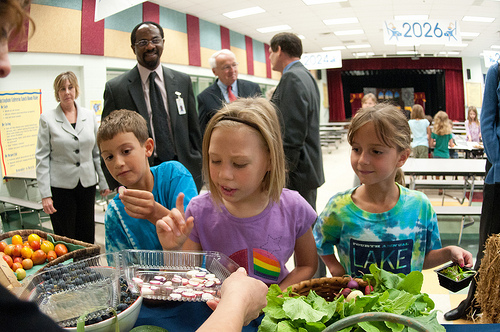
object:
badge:
[175, 91, 187, 116]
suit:
[101, 62, 204, 179]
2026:
[402, 22, 443, 37]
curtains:
[323, 56, 466, 123]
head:
[187, 95, 293, 205]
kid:
[428, 110, 454, 158]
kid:
[463, 105, 484, 158]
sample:
[0, 233, 68, 280]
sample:
[37, 279, 112, 327]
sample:
[334, 274, 374, 302]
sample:
[439, 265, 477, 281]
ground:
[315, 129, 488, 325]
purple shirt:
[184, 188, 317, 287]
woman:
[35, 69, 105, 246]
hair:
[53, 71, 80, 102]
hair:
[270, 32, 304, 59]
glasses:
[133, 37, 165, 45]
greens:
[255, 263, 447, 331]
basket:
[277, 277, 368, 302]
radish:
[130, 270, 222, 300]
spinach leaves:
[367, 270, 431, 310]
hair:
[345, 103, 414, 186]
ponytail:
[395, 167, 406, 186]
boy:
[95, 108, 197, 268]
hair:
[97, 109, 151, 148]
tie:
[226, 85, 238, 103]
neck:
[136, 55, 160, 71]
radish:
[118, 186, 126, 196]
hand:
[119, 188, 156, 219]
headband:
[213, 116, 267, 135]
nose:
[218, 162, 234, 180]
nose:
[358, 151, 371, 165]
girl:
[155, 97, 319, 301]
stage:
[326, 57, 466, 126]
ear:
[395, 147, 411, 167]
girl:
[311, 102, 475, 295]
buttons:
[74, 149, 79, 154]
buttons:
[75, 162, 80, 168]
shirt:
[35, 101, 110, 199]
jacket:
[36, 101, 111, 200]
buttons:
[74, 136, 78, 141]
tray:
[17, 248, 250, 328]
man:
[99, 21, 203, 196]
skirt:
[49, 179, 97, 244]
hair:
[201, 96, 286, 200]